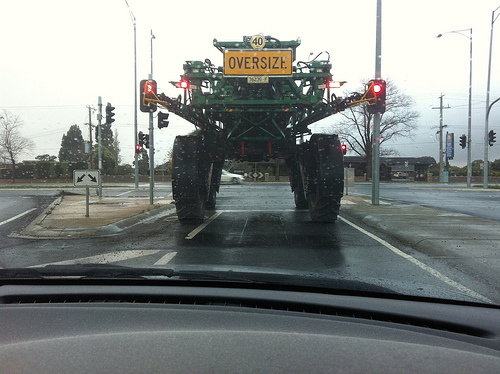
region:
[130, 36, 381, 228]
large green truck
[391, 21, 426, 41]
white clouds in blue sky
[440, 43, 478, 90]
white clouds in blue sky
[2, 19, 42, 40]
white clouds in blue sky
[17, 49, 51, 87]
white clouds in blue sky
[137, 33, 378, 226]
the vehicle is very large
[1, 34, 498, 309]
the very large vehicle on the road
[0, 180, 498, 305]
the white lines on the road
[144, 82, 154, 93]
the red light is on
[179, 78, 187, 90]
the red light is on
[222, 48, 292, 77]
the yellow rectangle sign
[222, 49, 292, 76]
the word OVERSIZE on the sign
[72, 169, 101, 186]
the sign with the black arrows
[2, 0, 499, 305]
the light poles on the road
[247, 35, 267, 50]
number 40 on the back of a truck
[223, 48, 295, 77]
yellow sign on the back of a truck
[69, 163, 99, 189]
white and black street sign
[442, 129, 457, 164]
sign in front of a business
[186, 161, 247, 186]
white car on the road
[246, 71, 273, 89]
license plate on the truck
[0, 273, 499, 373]
a grey dashboard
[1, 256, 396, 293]
a black windshield wiper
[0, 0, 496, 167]
a bright white sky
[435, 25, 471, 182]
a street light over the street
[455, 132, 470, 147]
a traffic light on the post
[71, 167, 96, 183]
a traffic sign on the median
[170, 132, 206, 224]
monster truck tires on the vehicle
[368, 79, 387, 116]
a traffic light at the intersection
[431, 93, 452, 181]
a telephone pole in the distance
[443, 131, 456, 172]
a business sign on the road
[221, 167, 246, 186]
a white car at the intersection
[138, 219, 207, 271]
traffic markers painted on the street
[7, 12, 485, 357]
view from behind a windshield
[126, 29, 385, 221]
huge black wheels on truck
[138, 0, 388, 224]
truck between two red traffic signals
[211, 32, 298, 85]
large sign between two small signs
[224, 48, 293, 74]
yellow sign on back of truck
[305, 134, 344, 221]
rear wheel on back of truck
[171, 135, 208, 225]
rear wheel on back of truck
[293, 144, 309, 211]
front wheel on back of truck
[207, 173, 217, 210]
front wheel on back of truck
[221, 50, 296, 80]
a yellow and black sign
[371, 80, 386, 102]
a bright red light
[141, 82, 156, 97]
a bright red light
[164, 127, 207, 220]
a large black tire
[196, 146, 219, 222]
a large black tire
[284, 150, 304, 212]
a large black tire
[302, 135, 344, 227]
a large black tire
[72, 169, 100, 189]
two black arrows on a sign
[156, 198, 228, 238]
a white line on pavement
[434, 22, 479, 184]
a tall street light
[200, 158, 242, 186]
a car on a street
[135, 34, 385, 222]
a car on a street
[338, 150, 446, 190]
a house on a street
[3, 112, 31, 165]
a tree in a field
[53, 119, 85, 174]
a tree in a field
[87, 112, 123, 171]
a tree in a field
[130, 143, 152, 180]
a tree in a field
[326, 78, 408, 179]
a tree in a field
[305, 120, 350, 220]
a big tire